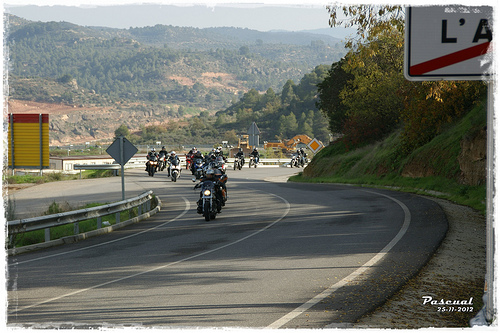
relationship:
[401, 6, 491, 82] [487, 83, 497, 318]
sign on pole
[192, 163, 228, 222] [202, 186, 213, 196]
bike has a light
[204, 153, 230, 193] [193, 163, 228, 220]
man on bike